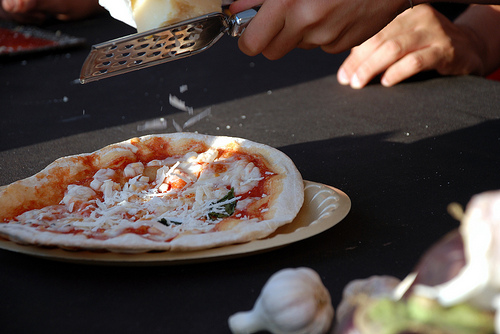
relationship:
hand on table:
[335, 2, 480, 91] [0, 20, 499, 332]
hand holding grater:
[230, 0, 414, 60] [77, 1, 269, 89]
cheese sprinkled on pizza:
[28, 156, 253, 232] [0, 128, 306, 253]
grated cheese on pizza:
[0, 133, 327, 262] [0, 128, 306, 253]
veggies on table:
[229, 221, 495, 327] [13, 43, 497, 330]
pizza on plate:
[0, 128, 306, 253] [0, 174, 355, 262]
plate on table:
[47, 105, 325, 271] [27, 40, 437, 267]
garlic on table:
[207, 257, 337, 331] [0, 20, 499, 332]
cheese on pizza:
[28, 156, 253, 232] [0, 128, 306, 253]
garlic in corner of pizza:
[226, 264, 337, 334] [42, 107, 315, 281]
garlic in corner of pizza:
[226, 264, 337, 334] [0, 128, 306, 253]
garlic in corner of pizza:
[450, 190, 499, 306] [0, 128, 306, 253]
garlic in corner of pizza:
[67, 183, 94, 201] [0, 128, 306, 253]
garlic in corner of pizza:
[83, 22, 230, 64] [0, 128, 306, 253]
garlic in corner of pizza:
[226, 264, 337, 334] [2, 115, 308, 278]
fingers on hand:
[313, 27, 480, 97] [335, 2, 480, 91]